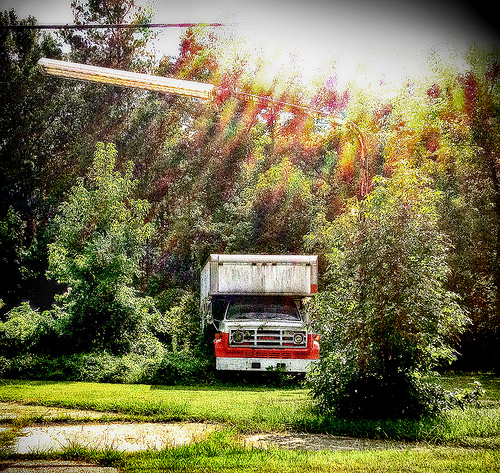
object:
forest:
[1, 3, 24, 361]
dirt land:
[18, 421, 48, 466]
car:
[198, 255, 324, 372]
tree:
[304, 162, 459, 444]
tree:
[256, 164, 320, 259]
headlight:
[293, 331, 304, 344]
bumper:
[217, 356, 315, 371]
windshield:
[223, 296, 301, 322]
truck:
[198, 253, 320, 386]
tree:
[153, 275, 202, 370]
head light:
[229, 326, 247, 345]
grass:
[267, 381, 309, 430]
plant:
[297, 157, 489, 442]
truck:
[195, 249, 322, 383]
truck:
[200, 245, 324, 381]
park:
[3, 0, 494, 472]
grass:
[123, 383, 193, 415]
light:
[36, 54, 214, 103]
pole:
[230, 87, 331, 121]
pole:
[339, 107, 385, 201]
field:
[456, 397, 497, 471]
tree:
[0, 140, 168, 382]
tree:
[459, 71, 500, 330]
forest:
[51, 10, 124, 327]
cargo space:
[197, 250, 317, 308]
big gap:
[18, 414, 218, 446]